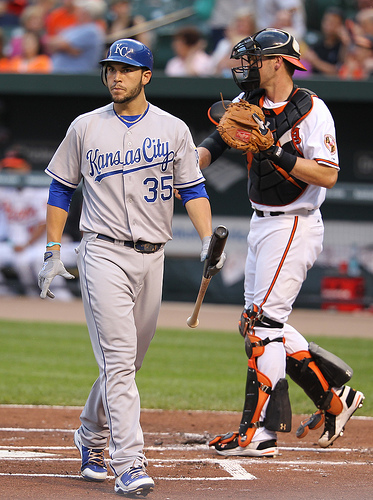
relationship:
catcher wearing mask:
[161, 26, 368, 462] [231, 36, 262, 91]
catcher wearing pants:
[161, 26, 368, 462] [241, 210, 329, 439]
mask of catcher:
[231, 36, 262, 91] [161, 26, 368, 462]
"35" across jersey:
[140, 174, 174, 205] [43, 99, 206, 243]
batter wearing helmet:
[37, 32, 235, 498] [100, 38, 154, 83]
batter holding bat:
[37, 32, 235, 498] [185, 222, 229, 329]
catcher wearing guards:
[161, 26, 368, 462] [206, 303, 296, 448]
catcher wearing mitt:
[161, 26, 368, 462] [217, 98, 274, 156]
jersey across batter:
[43, 99, 206, 243] [37, 32, 235, 498]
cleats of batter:
[71, 423, 157, 496] [37, 32, 235, 498]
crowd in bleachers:
[2, 1, 373, 77] [5, 4, 361, 94]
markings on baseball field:
[162, 427, 254, 489] [2, 292, 369, 499]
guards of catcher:
[239, 303, 296, 468] [161, 26, 368, 462]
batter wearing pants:
[37, 32, 235, 498] [241, 210, 329, 439]